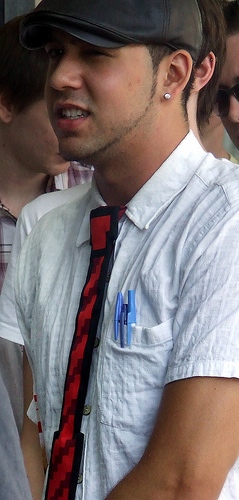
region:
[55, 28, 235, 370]
this is a man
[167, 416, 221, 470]
the man is light skinned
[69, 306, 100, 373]
this is a neck tie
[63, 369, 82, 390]
the tie is red in color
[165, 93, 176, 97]
this is a earing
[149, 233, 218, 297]
this is a shirt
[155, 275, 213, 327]
the shirt is white in color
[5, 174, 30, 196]
the lady is light skinned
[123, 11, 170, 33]
this is a cap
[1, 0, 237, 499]
Young adult male in red and black ties.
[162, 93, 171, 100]
A earring in a person's ear.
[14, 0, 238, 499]
A person wearing a white shirt.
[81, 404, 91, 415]
A button on a shirt.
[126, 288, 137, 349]
A ink pen in a pocket.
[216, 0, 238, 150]
A person wearing sunglasses.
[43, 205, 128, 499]
A red and black tie.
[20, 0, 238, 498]
A person wearing a black hat.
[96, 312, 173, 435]
A pocket on a shirt.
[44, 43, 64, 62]
A eye of a person.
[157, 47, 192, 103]
A ear of a person.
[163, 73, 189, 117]
This is an earing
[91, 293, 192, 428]
These are three pens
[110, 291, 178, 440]
The pens are blue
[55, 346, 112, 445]
This is a tie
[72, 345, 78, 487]
The tie is red and black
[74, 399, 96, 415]
This is a button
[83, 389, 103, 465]
The button is round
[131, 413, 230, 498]
This is an elbow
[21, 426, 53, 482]
This is an arm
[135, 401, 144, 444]
The shirt is wrinkled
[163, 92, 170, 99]
guy in front has diamond earring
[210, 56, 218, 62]
person has cartlidge piercing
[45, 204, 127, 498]
Tie is black and red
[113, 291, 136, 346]
three blue lidded pens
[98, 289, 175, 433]
pens are in shirt pocket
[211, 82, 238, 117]
person is wearing sunglasses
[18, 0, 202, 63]
person is wearing black hat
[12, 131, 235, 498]
person is wearing white button up shirt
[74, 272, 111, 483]
four buttons behind tie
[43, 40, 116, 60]
person has one eye closed